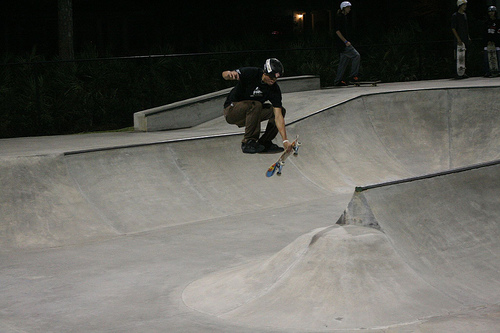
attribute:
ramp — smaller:
[2, 76, 494, 326]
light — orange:
[294, 12, 305, 19]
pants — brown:
[215, 99, 285, 143]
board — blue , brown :
[263, 135, 300, 177]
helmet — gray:
[262, 52, 286, 77]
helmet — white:
[338, 0, 350, 10]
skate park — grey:
[0, 73, 496, 331]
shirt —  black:
[223, 65, 282, 110]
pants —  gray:
[224, 98, 285, 140]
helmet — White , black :
[263, 53, 286, 82]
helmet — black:
[254, 52, 284, 84]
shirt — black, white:
[222, 66, 281, 106]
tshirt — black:
[224, 62, 288, 106]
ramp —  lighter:
[275, 220, 422, 305]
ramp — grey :
[328, 82, 432, 197]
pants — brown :
[221, 95, 293, 145]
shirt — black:
[215, 60, 295, 122]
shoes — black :
[243, 134, 286, 155]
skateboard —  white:
[263, 134, 300, 177]